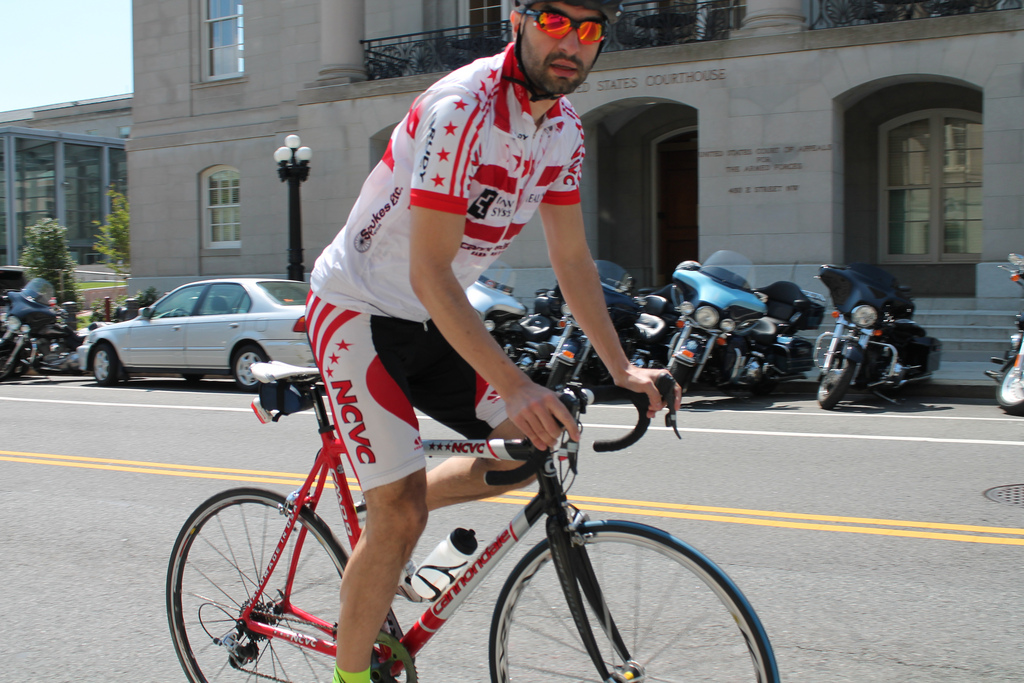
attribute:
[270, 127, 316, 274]
street lamp — street 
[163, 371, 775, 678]
bicycle — red and white 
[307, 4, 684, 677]
man — white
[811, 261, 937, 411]
motorcycle — large , black 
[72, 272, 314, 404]
car — silver 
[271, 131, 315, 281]
lamp pole — lamp 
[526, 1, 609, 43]
eye shades — pair , orange , eye 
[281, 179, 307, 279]
lamp pole — lamp , black 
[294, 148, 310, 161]
light — one 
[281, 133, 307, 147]
light — one 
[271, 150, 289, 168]
light — one 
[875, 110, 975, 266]
large window — large 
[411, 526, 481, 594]
water bottle — white , water 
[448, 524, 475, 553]
black cap — black 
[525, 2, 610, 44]
sunglasses — orange 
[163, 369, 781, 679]
bike — red and black 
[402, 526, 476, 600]
water bottle — white , water 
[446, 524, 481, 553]
black cap — cap 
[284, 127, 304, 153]
street lamp — white 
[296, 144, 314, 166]
street lamp — white 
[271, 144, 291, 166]
street lamp — white 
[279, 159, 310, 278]
metal pole — metal 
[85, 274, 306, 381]
silver car — silver , parked 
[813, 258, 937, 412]
parked motorcycle — parked 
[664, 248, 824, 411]
parked motorcycle — parked 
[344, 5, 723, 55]
railing — black, metal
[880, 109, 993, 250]
window — closed, white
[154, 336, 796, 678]
bicycle — red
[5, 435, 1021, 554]
line — double-yellow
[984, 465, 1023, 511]
manhole cover — metal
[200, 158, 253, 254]
window — white-framed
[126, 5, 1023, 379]
building — large , white , United States courthouse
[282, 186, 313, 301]
pole — metal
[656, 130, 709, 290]
door — large, dark-colored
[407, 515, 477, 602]
bottle — white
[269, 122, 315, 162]
light covers — white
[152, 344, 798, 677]
bike — red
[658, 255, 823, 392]
motorcycle — blue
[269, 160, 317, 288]
pole — black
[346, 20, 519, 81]
barrier railing — black